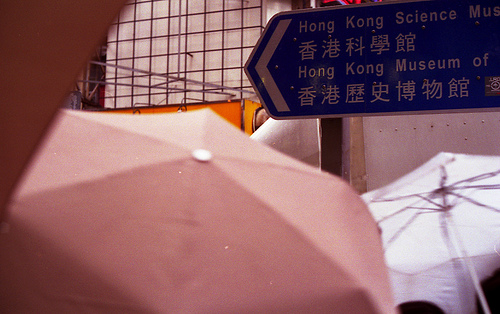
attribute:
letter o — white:
[307, 67, 317, 77]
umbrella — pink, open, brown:
[0, 106, 395, 312]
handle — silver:
[442, 205, 492, 313]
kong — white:
[344, 58, 390, 80]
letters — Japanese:
[291, 28, 470, 111]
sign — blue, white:
[243, 8, 497, 122]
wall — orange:
[69, 96, 275, 156]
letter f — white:
[478, 45, 495, 72]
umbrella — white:
[328, 135, 499, 311]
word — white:
[395, 53, 461, 72]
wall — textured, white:
[102, 0, 289, 110]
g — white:
[326, 64, 334, 81]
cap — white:
[165, 125, 236, 182]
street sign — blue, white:
[246, 4, 498, 113]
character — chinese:
[295, 32, 318, 59]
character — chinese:
[389, 79, 421, 109]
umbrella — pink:
[26, 123, 273, 310]